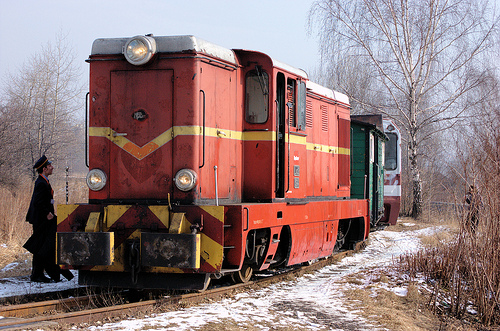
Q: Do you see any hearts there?
A: Yes, there is a heart.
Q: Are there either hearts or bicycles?
A: Yes, there is a heart.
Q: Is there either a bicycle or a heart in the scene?
A: Yes, there is a heart.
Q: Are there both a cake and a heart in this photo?
A: No, there is a heart but no cakes.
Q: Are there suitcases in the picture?
A: No, there are no suitcases.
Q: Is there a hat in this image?
A: Yes, there is a hat.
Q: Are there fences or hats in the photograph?
A: Yes, there is a hat.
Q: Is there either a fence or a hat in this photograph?
A: Yes, there is a hat.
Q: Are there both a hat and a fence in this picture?
A: No, there is a hat but no fences.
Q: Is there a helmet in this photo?
A: No, there are no helmets.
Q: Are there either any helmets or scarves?
A: No, there are no helmets or scarves.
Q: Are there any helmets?
A: No, there are no helmets.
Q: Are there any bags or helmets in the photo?
A: No, there are no helmets or bags.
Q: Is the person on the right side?
A: Yes, the person is on the right of the image.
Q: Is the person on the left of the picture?
A: No, the person is on the right of the image.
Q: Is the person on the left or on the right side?
A: The person is on the right of the image.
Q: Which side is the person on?
A: The person is on the right of the image.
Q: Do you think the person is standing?
A: Yes, the person is standing.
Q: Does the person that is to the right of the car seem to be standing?
A: Yes, the person is standing.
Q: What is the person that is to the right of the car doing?
A: The person is standing.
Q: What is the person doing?
A: The person is standing.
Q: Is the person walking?
A: No, the person is standing.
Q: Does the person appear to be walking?
A: No, the person is standing.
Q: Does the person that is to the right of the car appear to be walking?
A: No, the person is standing.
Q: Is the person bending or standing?
A: The person is standing.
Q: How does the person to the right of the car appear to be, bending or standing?
A: The person is standing.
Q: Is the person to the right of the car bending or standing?
A: The person is standing.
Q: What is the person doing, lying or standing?
A: The person is standing.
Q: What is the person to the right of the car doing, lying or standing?
A: The person is standing.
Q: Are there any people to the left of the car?
A: No, the person is to the right of the car.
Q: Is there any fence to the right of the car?
A: No, there is a person to the right of the car.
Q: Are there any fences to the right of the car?
A: No, there is a person to the right of the car.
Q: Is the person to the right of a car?
A: Yes, the person is to the right of a car.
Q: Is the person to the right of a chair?
A: No, the person is to the right of a car.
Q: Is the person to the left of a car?
A: No, the person is to the right of a car.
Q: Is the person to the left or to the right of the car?
A: The person is to the right of the car.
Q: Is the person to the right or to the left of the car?
A: The person is to the right of the car.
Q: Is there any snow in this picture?
A: Yes, there is snow.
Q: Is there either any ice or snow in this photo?
A: Yes, there is snow.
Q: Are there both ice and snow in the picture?
A: No, there is snow but no ice.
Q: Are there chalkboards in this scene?
A: No, there are no chalkboards.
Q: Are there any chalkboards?
A: No, there are no chalkboards.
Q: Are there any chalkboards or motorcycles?
A: No, there are no chalkboards or motorcycles.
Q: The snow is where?
A: The snow is on the ground.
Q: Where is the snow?
A: The snow is on the ground.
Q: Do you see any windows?
A: Yes, there is a window.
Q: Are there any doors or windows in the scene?
A: Yes, there is a window.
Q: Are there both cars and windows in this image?
A: Yes, there are both a window and a car.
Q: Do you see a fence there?
A: No, there are no fences.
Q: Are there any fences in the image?
A: No, there are no fences.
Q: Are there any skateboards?
A: No, there are no skateboards.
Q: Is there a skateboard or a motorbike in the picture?
A: No, there are no skateboards or motorcycles.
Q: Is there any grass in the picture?
A: Yes, there is grass.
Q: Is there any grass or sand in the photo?
A: Yes, there is grass.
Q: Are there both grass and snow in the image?
A: Yes, there are both grass and snow.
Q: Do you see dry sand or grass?
A: Yes, there is dry grass.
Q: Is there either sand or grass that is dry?
A: Yes, the grass is dry.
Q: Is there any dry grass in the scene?
A: Yes, there is dry grass.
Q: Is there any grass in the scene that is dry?
A: Yes, there is grass that is dry.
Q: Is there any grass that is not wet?
A: Yes, there is dry grass.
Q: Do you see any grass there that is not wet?
A: Yes, there is dry grass.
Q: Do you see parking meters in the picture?
A: No, there are no parking meters.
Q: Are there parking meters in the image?
A: No, there are no parking meters.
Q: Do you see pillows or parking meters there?
A: No, there are no parking meters or pillows.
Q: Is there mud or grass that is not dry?
A: No, there is grass but it is dry.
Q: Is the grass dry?
A: Yes, the grass is dry.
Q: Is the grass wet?
A: No, the grass is dry.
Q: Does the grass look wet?
A: No, the grass is dry.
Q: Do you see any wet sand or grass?
A: No, there is grass but it is dry.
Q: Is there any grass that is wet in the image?
A: No, there is grass but it is dry.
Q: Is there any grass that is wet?
A: No, there is grass but it is dry.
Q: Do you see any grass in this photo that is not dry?
A: No, there is grass but it is dry.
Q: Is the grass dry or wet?
A: The grass is dry.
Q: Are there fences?
A: No, there are no fences.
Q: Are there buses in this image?
A: No, there are no buses.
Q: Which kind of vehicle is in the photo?
A: The vehicle is a car.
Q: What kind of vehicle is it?
A: The vehicle is a car.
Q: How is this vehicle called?
A: This is a car.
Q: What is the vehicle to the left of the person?
A: The vehicle is a car.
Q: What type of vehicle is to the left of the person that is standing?
A: The vehicle is a car.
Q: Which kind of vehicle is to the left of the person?
A: The vehicle is a car.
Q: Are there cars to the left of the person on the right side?
A: Yes, there is a car to the left of the person.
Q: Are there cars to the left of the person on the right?
A: Yes, there is a car to the left of the person.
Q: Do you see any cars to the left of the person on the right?
A: Yes, there is a car to the left of the person.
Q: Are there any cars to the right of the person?
A: No, the car is to the left of the person.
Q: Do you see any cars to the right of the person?
A: No, the car is to the left of the person.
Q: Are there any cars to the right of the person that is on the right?
A: No, the car is to the left of the person.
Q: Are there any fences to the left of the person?
A: No, there is a car to the left of the person.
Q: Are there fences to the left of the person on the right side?
A: No, there is a car to the left of the person.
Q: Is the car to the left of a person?
A: Yes, the car is to the left of a person.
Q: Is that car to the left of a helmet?
A: No, the car is to the left of a person.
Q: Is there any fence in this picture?
A: No, there are no fences.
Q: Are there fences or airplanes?
A: No, there are no fences or airplanes.